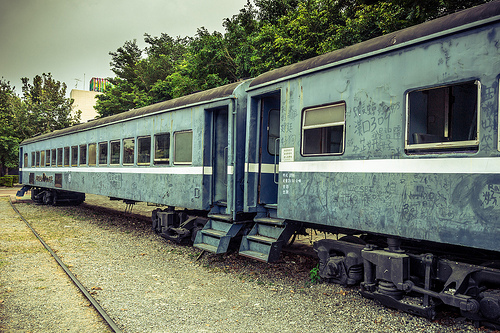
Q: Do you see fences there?
A: No, there are no fences.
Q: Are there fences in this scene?
A: No, there are no fences.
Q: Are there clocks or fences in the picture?
A: No, there are no fences or clocks.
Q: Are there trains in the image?
A: Yes, there are trains.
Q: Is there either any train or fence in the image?
A: Yes, there are trains.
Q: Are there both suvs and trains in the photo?
A: No, there are trains but no suvs.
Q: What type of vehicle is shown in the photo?
A: The vehicle is trains.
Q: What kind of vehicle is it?
A: The vehicles are trains.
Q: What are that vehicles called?
A: These are trains.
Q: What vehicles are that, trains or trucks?
A: These are trains.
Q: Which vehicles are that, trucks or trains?
A: These are trains.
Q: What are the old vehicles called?
A: The vehicles are trains.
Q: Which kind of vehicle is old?
A: The vehicle is trains.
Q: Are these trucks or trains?
A: These are trains.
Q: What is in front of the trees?
A: The trains are in front of the trees.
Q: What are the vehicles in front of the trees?
A: The vehicles are trains.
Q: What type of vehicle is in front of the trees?
A: The vehicles are trains.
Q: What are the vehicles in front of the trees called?
A: The vehicles are trains.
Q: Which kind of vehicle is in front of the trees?
A: The vehicles are trains.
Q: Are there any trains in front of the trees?
A: Yes, there are trains in front of the trees.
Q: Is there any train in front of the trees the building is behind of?
A: Yes, there are trains in front of the trees.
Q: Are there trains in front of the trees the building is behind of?
A: Yes, there are trains in front of the trees.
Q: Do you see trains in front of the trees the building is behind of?
A: Yes, there are trains in front of the trees.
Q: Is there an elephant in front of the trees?
A: No, there are trains in front of the trees.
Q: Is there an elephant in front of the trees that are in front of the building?
A: No, there are trains in front of the trees.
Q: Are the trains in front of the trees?
A: Yes, the trains are in front of the trees.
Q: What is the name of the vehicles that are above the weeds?
A: The vehicles are trains.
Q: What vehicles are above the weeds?
A: The vehicles are trains.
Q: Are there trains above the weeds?
A: Yes, there are trains above the weeds.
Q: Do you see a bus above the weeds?
A: No, there are trains above the weeds.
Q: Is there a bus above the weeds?
A: No, there are trains above the weeds.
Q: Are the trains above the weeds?
A: Yes, the trains are above the weeds.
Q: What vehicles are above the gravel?
A: The vehicles are trains.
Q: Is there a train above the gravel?
A: Yes, there are trains above the gravel.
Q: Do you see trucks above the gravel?
A: No, there are trains above the gravel.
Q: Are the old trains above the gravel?
A: Yes, the trains are above the gravel.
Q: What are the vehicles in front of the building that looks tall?
A: The vehicles are trains.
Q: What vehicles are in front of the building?
A: The vehicles are trains.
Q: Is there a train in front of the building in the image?
A: Yes, there are trains in front of the building.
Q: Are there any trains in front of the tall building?
A: Yes, there are trains in front of the building.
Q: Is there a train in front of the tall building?
A: Yes, there are trains in front of the building.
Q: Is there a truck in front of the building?
A: No, there are trains in front of the building.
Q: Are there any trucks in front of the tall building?
A: No, there are trains in front of the building.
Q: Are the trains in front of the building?
A: Yes, the trains are in front of the building.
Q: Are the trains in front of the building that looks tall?
A: Yes, the trains are in front of the building.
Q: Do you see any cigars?
A: No, there are no cigars.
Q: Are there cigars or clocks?
A: No, there are no cigars or clocks.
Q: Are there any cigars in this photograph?
A: No, there are no cigars.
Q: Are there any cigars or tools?
A: No, there are no cigars or tools.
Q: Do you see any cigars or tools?
A: No, there are no cigars or tools.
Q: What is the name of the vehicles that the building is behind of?
A: The vehicles are trains.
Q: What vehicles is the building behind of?
A: The building is behind the trains.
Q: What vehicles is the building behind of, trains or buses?
A: The building is behind trains.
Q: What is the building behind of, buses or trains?
A: The building is behind trains.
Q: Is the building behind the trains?
A: Yes, the building is behind the trains.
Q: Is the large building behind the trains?
A: Yes, the building is behind the trains.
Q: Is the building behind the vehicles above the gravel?
A: Yes, the building is behind the trains.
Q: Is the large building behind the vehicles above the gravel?
A: Yes, the building is behind the trains.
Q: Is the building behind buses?
A: No, the building is behind the trains.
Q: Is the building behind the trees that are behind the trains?
A: Yes, the building is behind the trees.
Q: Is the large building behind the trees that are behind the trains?
A: Yes, the building is behind the trees.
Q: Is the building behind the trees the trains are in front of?
A: Yes, the building is behind the trees.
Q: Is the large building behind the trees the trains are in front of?
A: Yes, the building is behind the trees.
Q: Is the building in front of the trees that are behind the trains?
A: No, the building is behind the trees.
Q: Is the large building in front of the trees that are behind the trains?
A: No, the building is behind the trees.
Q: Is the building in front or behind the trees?
A: The building is behind the trees.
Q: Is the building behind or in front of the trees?
A: The building is behind the trees.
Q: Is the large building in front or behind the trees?
A: The building is behind the trees.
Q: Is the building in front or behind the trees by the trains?
A: The building is behind the trees.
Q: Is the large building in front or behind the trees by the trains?
A: The building is behind the trees.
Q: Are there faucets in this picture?
A: No, there are no faucets.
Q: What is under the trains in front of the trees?
A: The gravel is under the trains.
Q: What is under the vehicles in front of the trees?
A: The gravel is under the trains.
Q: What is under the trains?
A: The gravel is under the trains.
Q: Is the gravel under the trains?
A: Yes, the gravel is under the trains.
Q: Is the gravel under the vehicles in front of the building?
A: Yes, the gravel is under the trains.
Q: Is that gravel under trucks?
A: No, the gravel is under the trains.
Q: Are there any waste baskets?
A: No, there are no waste baskets.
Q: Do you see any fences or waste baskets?
A: No, there are no waste baskets or fences.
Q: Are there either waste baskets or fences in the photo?
A: No, there are no waste baskets or fences.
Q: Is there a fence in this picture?
A: No, there are no fences.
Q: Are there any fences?
A: No, there are no fences.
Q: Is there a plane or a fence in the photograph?
A: No, there are no fences or airplanes.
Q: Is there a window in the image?
A: Yes, there are windows.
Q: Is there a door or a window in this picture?
A: Yes, there are windows.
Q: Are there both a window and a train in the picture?
A: Yes, there are both a window and a train.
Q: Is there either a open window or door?
A: Yes, there are open windows.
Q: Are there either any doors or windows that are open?
A: Yes, the windows are open.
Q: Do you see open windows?
A: Yes, there are open windows.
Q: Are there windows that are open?
A: Yes, there are windows that are open.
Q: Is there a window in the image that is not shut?
A: Yes, there are open windows.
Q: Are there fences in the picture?
A: No, there are no fences.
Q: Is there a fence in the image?
A: No, there are no fences.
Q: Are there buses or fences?
A: No, there are no fences or buses.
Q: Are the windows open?
A: Yes, the windows are open.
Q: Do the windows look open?
A: Yes, the windows are open.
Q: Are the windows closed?
A: No, the windows are open.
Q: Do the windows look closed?
A: No, the windows are open.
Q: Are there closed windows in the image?
A: No, there are windows but they are open.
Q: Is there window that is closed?
A: No, there are windows but they are open.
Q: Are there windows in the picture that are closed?
A: No, there are windows but they are open.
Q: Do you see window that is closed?
A: No, there are windows but they are open.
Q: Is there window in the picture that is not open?
A: No, there are windows but they are open.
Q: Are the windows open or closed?
A: The windows are open.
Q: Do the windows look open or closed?
A: The windows are open.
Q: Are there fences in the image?
A: No, there are no fences.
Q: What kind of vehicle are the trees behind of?
A: The trees are behind the trains.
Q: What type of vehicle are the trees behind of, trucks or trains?
A: The trees are behind trains.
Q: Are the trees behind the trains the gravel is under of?
A: Yes, the trees are behind the trains.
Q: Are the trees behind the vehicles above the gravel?
A: Yes, the trees are behind the trains.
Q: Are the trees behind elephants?
A: No, the trees are behind the trains.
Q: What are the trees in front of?
A: The trees are in front of the building.